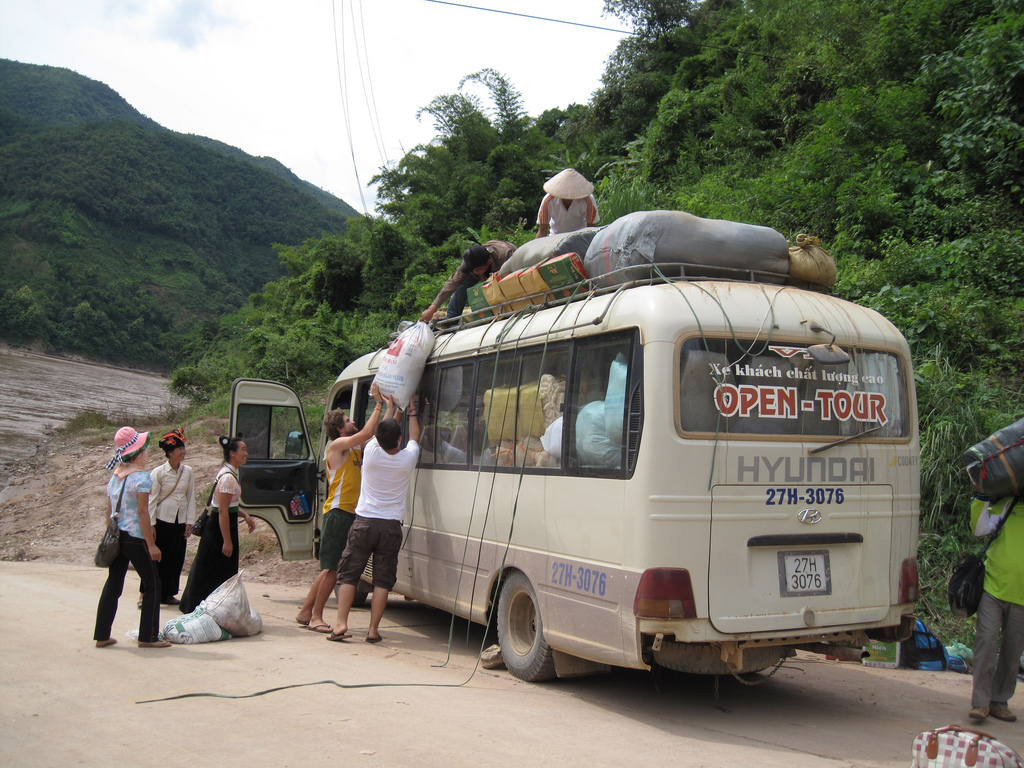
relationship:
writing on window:
[719, 388, 884, 410] [681, 352, 898, 439]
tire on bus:
[492, 565, 545, 697] [196, 262, 940, 706]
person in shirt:
[944, 411, 1022, 733] [966, 498, 1021, 600]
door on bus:
[224, 376, 335, 558] [210, 327, 924, 667]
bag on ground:
[155, 606, 231, 637] [13, 606, 402, 764]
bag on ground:
[201, 567, 262, 628] [13, 606, 402, 764]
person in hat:
[106, 405, 169, 648] [104, 415, 154, 465]